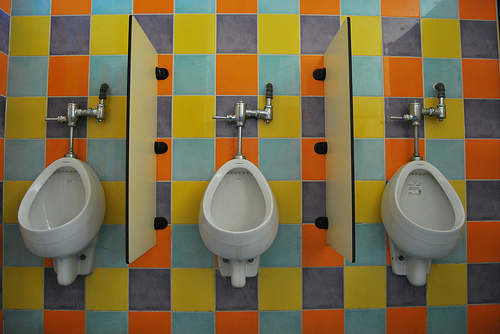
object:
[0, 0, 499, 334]
wall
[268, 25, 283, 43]
color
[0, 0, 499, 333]
multi color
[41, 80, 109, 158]
plumbing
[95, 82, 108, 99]
handle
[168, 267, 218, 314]
tile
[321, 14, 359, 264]
dividers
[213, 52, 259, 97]
square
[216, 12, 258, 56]
square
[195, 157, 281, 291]
urinal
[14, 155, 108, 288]
urinal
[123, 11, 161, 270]
urinal divider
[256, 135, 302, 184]
tile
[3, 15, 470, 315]
floor